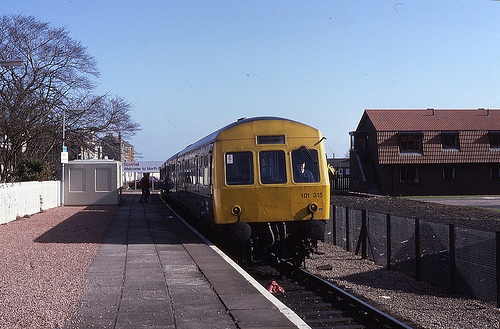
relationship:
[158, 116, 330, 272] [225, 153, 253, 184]
train has window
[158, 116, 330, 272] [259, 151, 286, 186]
train has window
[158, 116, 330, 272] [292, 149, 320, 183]
train has window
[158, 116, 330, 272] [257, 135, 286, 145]
train has window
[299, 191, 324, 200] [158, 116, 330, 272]
number painted on train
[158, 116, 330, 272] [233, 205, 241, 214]
train has light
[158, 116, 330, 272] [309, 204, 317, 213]
train has light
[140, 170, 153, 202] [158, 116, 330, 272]
people waiting to board train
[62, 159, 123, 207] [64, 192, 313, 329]
building next to platform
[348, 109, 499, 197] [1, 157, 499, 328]
building near train station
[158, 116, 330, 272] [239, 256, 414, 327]
train on top of track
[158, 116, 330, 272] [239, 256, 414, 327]
train going down track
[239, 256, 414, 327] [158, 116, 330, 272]
track under train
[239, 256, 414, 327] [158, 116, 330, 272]
track with train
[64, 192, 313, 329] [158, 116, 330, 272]
platform next to train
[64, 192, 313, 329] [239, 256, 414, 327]
platform next to track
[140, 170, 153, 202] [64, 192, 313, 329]
people standing on platform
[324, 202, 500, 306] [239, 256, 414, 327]
fence next to track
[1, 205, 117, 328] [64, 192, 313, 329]
rocks next to platform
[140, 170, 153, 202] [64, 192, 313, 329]
people on top of platform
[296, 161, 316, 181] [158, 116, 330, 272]
engineer inside train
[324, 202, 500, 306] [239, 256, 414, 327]
fence beside track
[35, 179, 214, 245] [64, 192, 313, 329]
shadow on platform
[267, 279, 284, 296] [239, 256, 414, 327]
object on top of track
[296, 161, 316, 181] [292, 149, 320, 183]
engineer behind window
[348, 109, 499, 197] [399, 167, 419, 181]
building has window